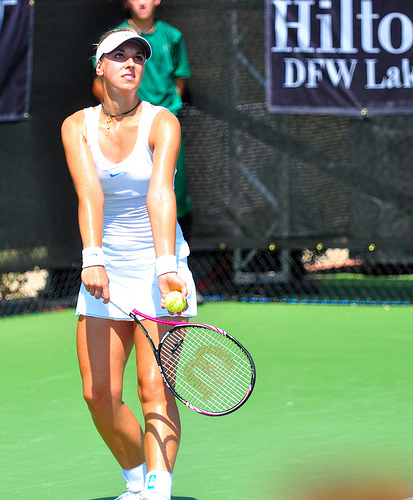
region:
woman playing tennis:
[58, 28, 199, 498]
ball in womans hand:
[161, 287, 189, 314]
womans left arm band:
[148, 249, 176, 274]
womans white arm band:
[77, 241, 108, 272]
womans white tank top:
[74, 99, 191, 255]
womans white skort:
[73, 255, 199, 328]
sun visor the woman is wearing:
[90, 27, 154, 62]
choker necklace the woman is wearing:
[100, 98, 142, 119]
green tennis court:
[0, 297, 412, 498]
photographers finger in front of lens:
[277, 474, 410, 498]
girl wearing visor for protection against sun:
[94, 27, 151, 61]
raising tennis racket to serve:
[100, 285, 254, 415]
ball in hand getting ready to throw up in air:
[160, 292, 188, 310]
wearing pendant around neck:
[98, 98, 142, 122]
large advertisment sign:
[266, 0, 411, 107]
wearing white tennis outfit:
[76, 101, 199, 319]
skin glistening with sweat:
[61, 102, 182, 477]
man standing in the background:
[104, 0, 191, 114]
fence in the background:
[1, 107, 411, 303]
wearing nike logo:
[98, 155, 138, 188]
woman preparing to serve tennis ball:
[49, 23, 261, 499]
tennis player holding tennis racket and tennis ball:
[53, 19, 271, 498]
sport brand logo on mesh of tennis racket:
[176, 334, 239, 403]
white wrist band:
[74, 243, 109, 269]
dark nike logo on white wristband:
[86, 249, 100, 259]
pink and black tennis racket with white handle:
[88, 293, 260, 419]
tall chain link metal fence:
[1, 0, 411, 319]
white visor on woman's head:
[84, 28, 154, 64]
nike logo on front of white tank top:
[103, 167, 133, 182]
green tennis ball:
[159, 287, 193, 317]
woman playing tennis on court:
[11, 26, 341, 471]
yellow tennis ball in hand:
[155, 285, 196, 313]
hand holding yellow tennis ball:
[146, 273, 198, 316]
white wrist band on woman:
[145, 249, 184, 280]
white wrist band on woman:
[78, 241, 108, 268]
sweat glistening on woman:
[52, 95, 184, 184]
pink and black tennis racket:
[104, 288, 264, 423]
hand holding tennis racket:
[57, 243, 274, 421]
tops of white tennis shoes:
[118, 481, 174, 495]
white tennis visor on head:
[80, 23, 162, 96]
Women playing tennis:
[50, 22, 202, 498]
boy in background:
[119, 0, 190, 121]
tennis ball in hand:
[151, 249, 202, 321]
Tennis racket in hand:
[69, 263, 263, 421]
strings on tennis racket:
[171, 342, 231, 380]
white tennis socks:
[116, 459, 178, 497]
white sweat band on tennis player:
[77, 239, 106, 267]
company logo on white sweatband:
[85, 249, 99, 257]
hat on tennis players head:
[91, 22, 152, 67]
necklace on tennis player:
[95, 94, 142, 144]